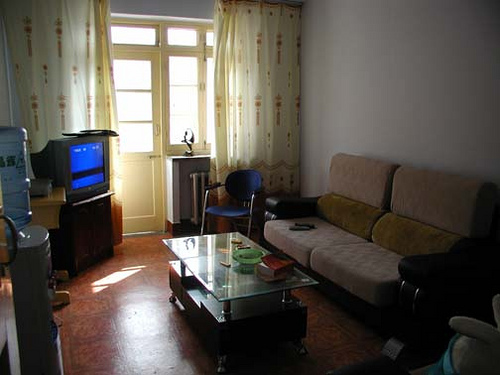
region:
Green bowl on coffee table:
[229, 244, 269, 267]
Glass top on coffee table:
[156, 218, 323, 322]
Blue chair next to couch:
[196, 160, 270, 235]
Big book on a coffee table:
[252, 246, 301, 286]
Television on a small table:
[31, 123, 121, 209]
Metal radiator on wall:
[184, 168, 202, 226]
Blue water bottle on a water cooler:
[1, 111, 39, 243]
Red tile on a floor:
[106, 303, 166, 353]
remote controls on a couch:
[283, 216, 323, 238]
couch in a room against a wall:
[263, 148, 496, 312]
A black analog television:
[40, 130, 129, 180]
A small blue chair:
[190, 176, 263, 212]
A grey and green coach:
[287, 151, 484, 287]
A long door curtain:
[215, 7, 314, 189]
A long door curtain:
[10, 7, 129, 185]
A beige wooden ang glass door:
[112, 13, 176, 248]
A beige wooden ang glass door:
[150, 5, 225, 221]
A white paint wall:
[324, 13, 395, 173]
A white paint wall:
[407, 19, 489, 162]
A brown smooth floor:
[68, 301, 168, 371]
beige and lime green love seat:
[256, 145, 496, 315]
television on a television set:
[30, 125, 156, 271]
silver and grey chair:
[187, 160, 282, 251]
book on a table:
[252, 250, 319, 302]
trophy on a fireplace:
[170, 125, 252, 223]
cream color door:
[95, 37, 170, 238]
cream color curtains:
[211, 26, 304, 187]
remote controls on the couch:
[260, 126, 496, 328]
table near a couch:
[157, 137, 497, 368]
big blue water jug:
[1, 114, 51, 233]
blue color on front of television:
[66, 144, 108, 191]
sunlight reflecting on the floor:
[89, 262, 160, 302]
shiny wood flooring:
[98, 314, 155, 347]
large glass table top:
[162, 225, 324, 301]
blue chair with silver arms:
[185, 166, 268, 214]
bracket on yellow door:
[138, 149, 170, 167]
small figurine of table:
[169, 121, 211, 157]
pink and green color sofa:
[286, 140, 459, 300]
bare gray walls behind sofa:
[316, 31, 453, 83]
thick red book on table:
[241, 246, 296, 266]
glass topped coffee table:
[157, 229, 334, 371]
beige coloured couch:
[259, 152, 496, 309]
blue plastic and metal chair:
[195, 170, 270, 237]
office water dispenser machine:
[0, 118, 68, 373]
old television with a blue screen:
[27, 122, 114, 204]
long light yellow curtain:
[200, 5, 304, 204]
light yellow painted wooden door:
[105, 50, 167, 240]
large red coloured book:
[253, 249, 299, 282]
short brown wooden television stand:
[57, 191, 117, 277]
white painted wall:
[292, 5, 498, 202]